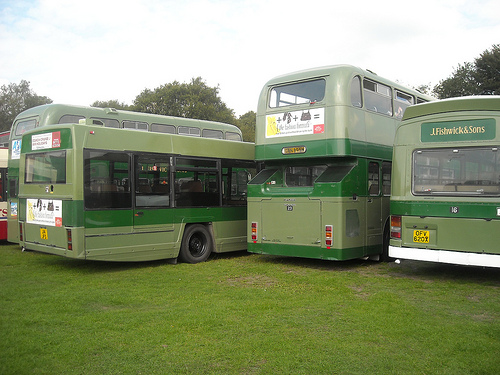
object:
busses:
[244, 63, 387, 263]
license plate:
[410, 227, 430, 246]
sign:
[261, 107, 330, 139]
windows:
[363, 79, 377, 91]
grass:
[2, 268, 498, 372]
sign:
[418, 117, 499, 143]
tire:
[184, 223, 214, 262]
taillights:
[324, 225, 333, 232]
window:
[267, 78, 328, 112]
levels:
[249, 61, 390, 163]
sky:
[2, 2, 481, 69]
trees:
[476, 44, 500, 87]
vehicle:
[387, 94, 498, 272]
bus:
[14, 124, 246, 265]